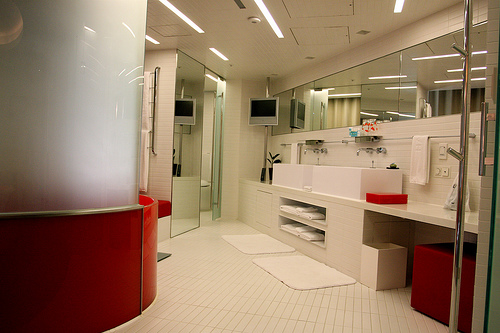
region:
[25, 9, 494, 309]
the room is mostly white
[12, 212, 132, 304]
this section of wall is red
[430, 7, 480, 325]
the pole is made of metal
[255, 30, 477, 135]
There is a mirror up top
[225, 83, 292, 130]
There is a monitor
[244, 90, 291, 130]
the monitor is off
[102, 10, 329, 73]
The lights are on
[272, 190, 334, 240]
There are towels in the shelf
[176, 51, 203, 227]
there is a large mirror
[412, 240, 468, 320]
the box is red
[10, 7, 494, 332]
a red and white bathroom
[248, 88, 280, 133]
a television in a bathroom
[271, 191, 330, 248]
towels on a shelf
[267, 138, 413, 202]
two white sinks in a bathroom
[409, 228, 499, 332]
a red seat under the counter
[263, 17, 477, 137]
a mirror on the wall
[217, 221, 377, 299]
two white rugs on the floor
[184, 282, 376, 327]
tile on the floor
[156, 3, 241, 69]
lights in the ceiling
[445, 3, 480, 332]
A chrome towel rack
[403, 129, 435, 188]
White towel on rack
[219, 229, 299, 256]
Bath mat on floor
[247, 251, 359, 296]
Bath mat on floor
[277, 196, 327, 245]
Folded towels on shelf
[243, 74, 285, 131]
Video monitor mounted on ceiling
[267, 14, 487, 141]
Mirror mounted on wall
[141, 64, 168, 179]
Metal towel rack with several towels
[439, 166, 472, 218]
Plastic bag on counter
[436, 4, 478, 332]
Metal clothes hanging pole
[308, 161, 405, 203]
elevated sink on counter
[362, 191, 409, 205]
Closed red box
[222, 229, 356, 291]
Two rectangular white bathroom rugs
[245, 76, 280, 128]
Silver television hanging from the ceiling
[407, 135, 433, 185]
White cotton hand towel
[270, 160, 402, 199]
Two rectangle sinks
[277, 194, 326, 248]
Folded bathroom towels on shelves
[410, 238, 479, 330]
Cube red ottoman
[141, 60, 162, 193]
Metal bath towel rack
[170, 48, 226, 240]
Glass bathroom doors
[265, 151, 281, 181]
Small plant in a pot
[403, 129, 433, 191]
White hanging hand towel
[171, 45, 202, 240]
Large floor to ceiling mirror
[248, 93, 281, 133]
A television mounted to the wall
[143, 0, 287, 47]
A white tile ceiling with fluorescent lighting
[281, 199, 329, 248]
White towels stored under vanity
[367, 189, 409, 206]
A small red box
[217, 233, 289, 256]
A white bath rug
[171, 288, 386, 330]
A white tiled floor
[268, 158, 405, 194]
Two white wash basin sinks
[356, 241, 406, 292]
A white trash receptacle